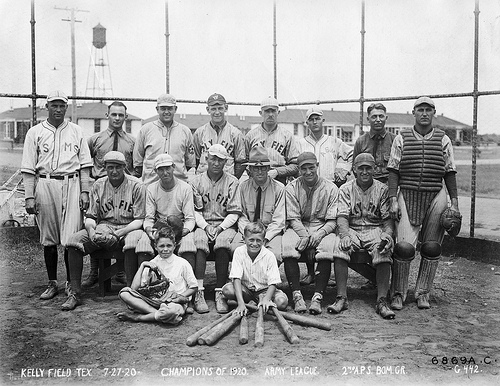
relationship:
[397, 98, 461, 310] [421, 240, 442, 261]
player wears knee-pad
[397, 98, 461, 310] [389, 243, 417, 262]
player wears knee-pad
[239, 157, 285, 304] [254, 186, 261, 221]
man wears tie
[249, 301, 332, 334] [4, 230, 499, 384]
bat on ground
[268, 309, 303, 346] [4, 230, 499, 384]
bat on ground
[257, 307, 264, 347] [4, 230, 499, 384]
bat on ground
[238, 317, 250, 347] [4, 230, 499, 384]
bat on ground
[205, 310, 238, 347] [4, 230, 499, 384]
bat on ground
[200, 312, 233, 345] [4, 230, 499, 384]
bat on ground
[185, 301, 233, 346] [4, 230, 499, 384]
bat on ground